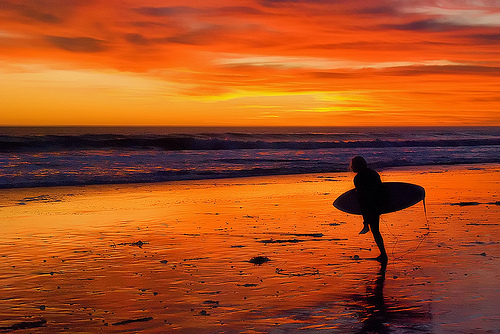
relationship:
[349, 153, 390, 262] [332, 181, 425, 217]
person holding surfboard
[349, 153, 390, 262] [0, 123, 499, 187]
person walking to water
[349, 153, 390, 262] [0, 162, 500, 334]
person in sand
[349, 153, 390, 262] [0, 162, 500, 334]
person standing on sand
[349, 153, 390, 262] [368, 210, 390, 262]
person has leg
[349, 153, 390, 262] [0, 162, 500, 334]
person on sand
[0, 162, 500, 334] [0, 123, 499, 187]
sand near water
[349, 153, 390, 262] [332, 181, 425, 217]
person has surfboard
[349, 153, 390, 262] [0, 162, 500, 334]
person walking on sand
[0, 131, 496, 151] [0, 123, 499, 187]
wave in water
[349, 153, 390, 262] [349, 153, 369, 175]
person has hair